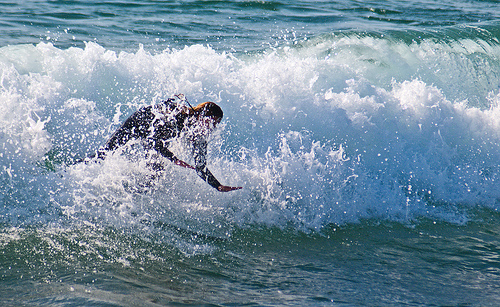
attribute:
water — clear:
[76, 0, 288, 45]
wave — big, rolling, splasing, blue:
[34, 43, 467, 94]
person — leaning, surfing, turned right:
[83, 91, 247, 202]